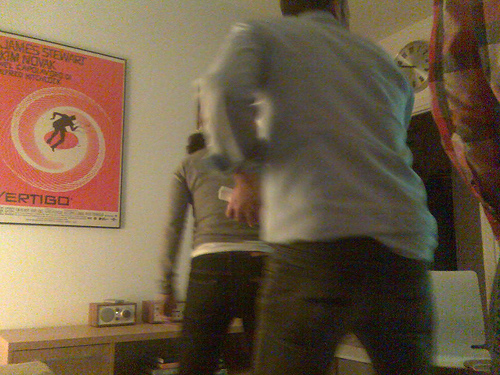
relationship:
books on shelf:
[141, 350, 176, 373] [5, 308, 252, 373]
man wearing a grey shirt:
[157, 19, 433, 321] [304, 120, 333, 230]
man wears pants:
[195, 12, 442, 375] [253, 227, 459, 373]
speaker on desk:
[87, 295, 142, 332] [2, 305, 252, 373]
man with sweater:
[176, 125, 280, 373] [167, 143, 267, 249]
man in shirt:
[195, 12, 442, 375] [198, 10, 445, 263]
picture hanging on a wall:
[0, 27, 130, 229] [1, 0, 272, 329]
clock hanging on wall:
[380, 31, 437, 95] [344, 12, 498, 367]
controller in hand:
[216, 183, 262, 208] [226, 170, 267, 228]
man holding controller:
[195, 12, 442, 375] [216, 183, 262, 208]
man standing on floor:
[176, 125, 280, 373] [0, 338, 500, 371]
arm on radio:
[153, 160, 190, 318] [141, 298, 186, 324]